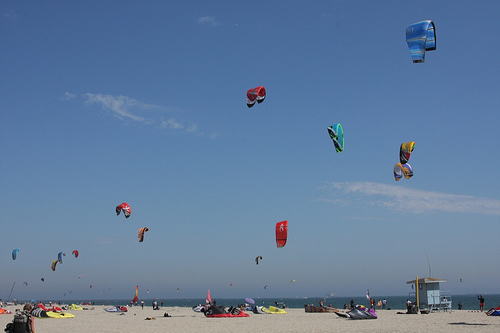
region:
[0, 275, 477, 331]
people are lying on the beach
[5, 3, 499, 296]
the bright blue sky filled with many kites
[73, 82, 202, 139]
the remains of a white cloud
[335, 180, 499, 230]
the one other white cloud in the sky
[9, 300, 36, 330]
a man wearing a back pack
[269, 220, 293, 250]
a red kite in the sky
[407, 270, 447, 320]
the lifeguard tower on the beach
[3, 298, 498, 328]
the beach filled with many people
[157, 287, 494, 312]
the ocean next to the beach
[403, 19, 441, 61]
the blue kite with a white stripe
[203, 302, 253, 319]
people laying on a red towel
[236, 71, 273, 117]
a colorful kite in a clear blue sky.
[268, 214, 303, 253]
a red kite in a blue sky.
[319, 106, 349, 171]
a blue kite in the sky.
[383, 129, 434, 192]
a multi colored kite in the sky.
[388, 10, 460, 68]
a flying blue kite.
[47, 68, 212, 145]
a white cloud in a blue sky.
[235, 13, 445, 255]
a section of blue sky with kites.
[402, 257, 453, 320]
a tall blue lifeguard tower.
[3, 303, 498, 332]
A sandy beach.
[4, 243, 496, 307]
hazy sky above a beach.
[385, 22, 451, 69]
stripes kite flying in the air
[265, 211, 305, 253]
red kite flying in the air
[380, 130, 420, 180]
colorful kite flying in the air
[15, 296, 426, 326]
people sunbathing at the beach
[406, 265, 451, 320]
life house in the middle of the beach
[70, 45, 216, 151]
few clouds in the sky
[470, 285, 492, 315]
man standing flying the kite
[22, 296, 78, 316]
lady laying in the sand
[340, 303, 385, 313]
gray jet-ski in the beach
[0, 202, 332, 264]
different kind of kite flying in the air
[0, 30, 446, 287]
Flying kites on the beach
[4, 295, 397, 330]
People laying out on beach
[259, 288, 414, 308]
Blue ocean in background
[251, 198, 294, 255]
Red kite flying in air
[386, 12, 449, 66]
Blue kite flying in air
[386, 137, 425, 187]
Yellow kite flying in air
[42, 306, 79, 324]
Kite on the beach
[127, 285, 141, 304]
Para-sail in the ocean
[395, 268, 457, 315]
Beach maintenance house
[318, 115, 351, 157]
Bright blue kite in sky